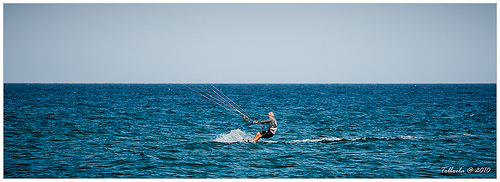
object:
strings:
[208, 83, 256, 118]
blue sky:
[4, 3, 499, 82]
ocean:
[3, 82, 496, 178]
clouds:
[4, 4, 499, 84]